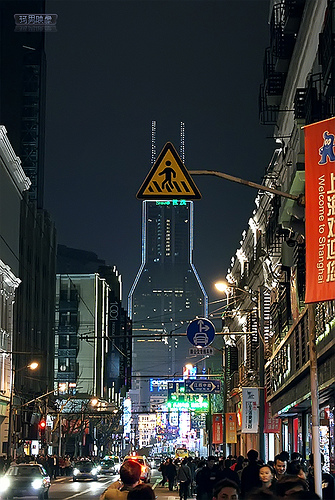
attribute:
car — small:
[69, 448, 106, 484]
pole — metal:
[183, 160, 296, 206]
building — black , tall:
[0, 19, 85, 457]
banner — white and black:
[241, 386, 259, 432]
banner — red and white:
[297, 114, 333, 307]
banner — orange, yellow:
[225, 410, 236, 443]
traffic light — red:
[36, 413, 46, 430]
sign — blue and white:
[183, 317, 216, 349]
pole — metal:
[136, 142, 301, 206]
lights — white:
[154, 188, 209, 237]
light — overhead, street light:
[23, 358, 39, 376]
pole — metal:
[189, 168, 300, 208]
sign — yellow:
[134, 139, 204, 203]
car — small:
[1, 459, 61, 491]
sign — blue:
[173, 307, 252, 419]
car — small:
[73, 460, 90, 479]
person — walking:
[255, 463, 276, 493]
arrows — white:
[195, 316, 208, 330]